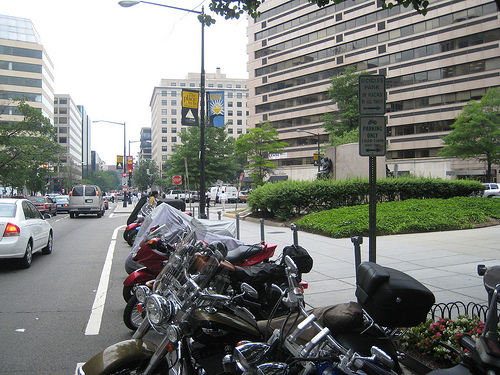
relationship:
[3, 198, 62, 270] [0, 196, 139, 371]
car on road